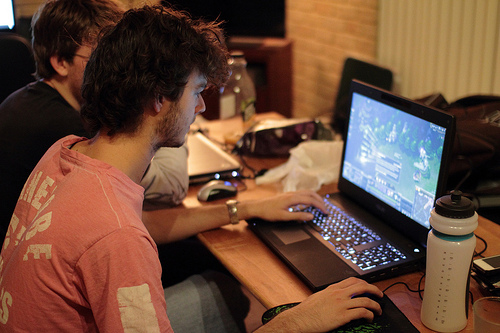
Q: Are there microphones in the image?
A: No, there are no microphones.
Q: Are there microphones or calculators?
A: No, there are no microphones or calculators.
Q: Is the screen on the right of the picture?
A: Yes, the screen is on the right of the image.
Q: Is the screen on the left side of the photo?
A: No, the screen is on the right of the image.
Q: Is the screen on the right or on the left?
A: The screen is on the right of the image.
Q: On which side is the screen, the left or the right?
A: The screen is on the right of the image.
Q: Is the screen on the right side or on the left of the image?
A: The screen is on the right of the image.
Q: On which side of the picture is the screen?
A: The screen is on the right of the image.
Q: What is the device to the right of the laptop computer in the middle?
A: The device is a screen.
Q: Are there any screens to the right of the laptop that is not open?
A: Yes, there is a screen to the right of the laptop.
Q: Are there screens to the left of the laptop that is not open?
A: No, the screen is to the right of the laptop computer.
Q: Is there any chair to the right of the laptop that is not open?
A: No, there is a screen to the right of the laptop computer.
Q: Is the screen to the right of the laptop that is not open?
A: Yes, the screen is to the right of the laptop.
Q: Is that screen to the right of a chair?
A: No, the screen is to the right of the laptop.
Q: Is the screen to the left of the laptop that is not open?
A: No, the screen is to the right of the laptop computer.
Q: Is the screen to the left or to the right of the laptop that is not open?
A: The screen is to the right of the laptop.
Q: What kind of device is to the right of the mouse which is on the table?
A: The device is a screen.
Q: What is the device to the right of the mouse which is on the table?
A: The device is a screen.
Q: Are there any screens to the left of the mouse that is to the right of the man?
A: No, the screen is to the right of the mouse.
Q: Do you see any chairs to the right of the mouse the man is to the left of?
A: No, there is a screen to the right of the computer mouse.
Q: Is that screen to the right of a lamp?
A: No, the screen is to the right of the mouse.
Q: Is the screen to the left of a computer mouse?
A: No, the screen is to the right of a computer mouse.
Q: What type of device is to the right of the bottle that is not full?
A: The device is a screen.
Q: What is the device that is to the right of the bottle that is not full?
A: The device is a screen.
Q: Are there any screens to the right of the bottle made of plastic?
A: Yes, there is a screen to the right of the bottle.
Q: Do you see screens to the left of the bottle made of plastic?
A: No, the screen is to the right of the bottle.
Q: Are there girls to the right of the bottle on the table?
A: No, there is a screen to the right of the bottle.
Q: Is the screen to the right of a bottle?
A: Yes, the screen is to the right of a bottle.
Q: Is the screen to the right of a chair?
A: No, the screen is to the right of a bottle.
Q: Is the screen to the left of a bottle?
A: No, the screen is to the right of a bottle.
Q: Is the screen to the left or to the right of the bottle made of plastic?
A: The screen is to the right of the bottle.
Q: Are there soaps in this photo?
A: No, there are no soaps.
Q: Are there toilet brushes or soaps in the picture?
A: No, there are no soaps or toilet brushes.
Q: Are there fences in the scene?
A: No, there are no fences.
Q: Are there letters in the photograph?
A: Yes, there are letters.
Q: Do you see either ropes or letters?
A: Yes, there are letters.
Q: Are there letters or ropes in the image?
A: Yes, there are letters.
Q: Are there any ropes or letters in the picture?
A: Yes, there are letters.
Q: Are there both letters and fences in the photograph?
A: No, there are letters but no fences.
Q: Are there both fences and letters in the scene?
A: No, there are letters but no fences.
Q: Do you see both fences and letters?
A: No, there are letters but no fences.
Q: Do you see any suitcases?
A: No, there are no suitcases.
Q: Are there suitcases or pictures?
A: No, there are no suitcases or pictures.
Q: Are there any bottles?
A: Yes, there is a bottle.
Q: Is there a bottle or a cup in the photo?
A: Yes, there is a bottle.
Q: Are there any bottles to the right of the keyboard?
A: Yes, there is a bottle to the right of the keyboard.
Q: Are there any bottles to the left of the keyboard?
A: No, the bottle is to the right of the keyboard.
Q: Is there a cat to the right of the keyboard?
A: No, there is a bottle to the right of the keyboard.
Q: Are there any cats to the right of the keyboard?
A: No, there is a bottle to the right of the keyboard.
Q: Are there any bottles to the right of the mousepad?
A: Yes, there is a bottle to the right of the mousepad.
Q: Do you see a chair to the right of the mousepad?
A: No, there is a bottle to the right of the mousepad.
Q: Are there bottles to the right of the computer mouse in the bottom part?
A: Yes, there is a bottle to the right of the mouse.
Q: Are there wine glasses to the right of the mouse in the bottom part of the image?
A: No, there is a bottle to the right of the mouse.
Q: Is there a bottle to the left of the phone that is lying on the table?
A: Yes, there is a bottle to the left of the telephone.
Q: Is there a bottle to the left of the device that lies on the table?
A: Yes, there is a bottle to the left of the telephone.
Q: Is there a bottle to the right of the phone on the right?
A: No, the bottle is to the left of the telephone.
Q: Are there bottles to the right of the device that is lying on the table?
A: No, the bottle is to the left of the telephone.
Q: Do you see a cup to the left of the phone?
A: No, there is a bottle to the left of the phone.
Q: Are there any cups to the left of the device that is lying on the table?
A: No, there is a bottle to the left of the phone.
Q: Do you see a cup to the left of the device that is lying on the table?
A: No, there is a bottle to the left of the phone.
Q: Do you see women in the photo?
A: No, there are no women.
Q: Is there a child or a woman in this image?
A: No, there are no women or children.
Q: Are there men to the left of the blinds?
A: Yes, there is a man to the left of the blinds.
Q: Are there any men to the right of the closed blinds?
A: No, the man is to the left of the blinds.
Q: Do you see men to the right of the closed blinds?
A: No, the man is to the left of the blinds.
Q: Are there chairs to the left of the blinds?
A: No, there is a man to the left of the blinds.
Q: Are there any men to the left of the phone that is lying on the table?
A: Yes, there is a man to the left of the phone.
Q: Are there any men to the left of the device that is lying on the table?
A: Yes, there is a man to the left of the phone.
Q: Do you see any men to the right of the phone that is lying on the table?
A: No, the man is to the left of the phone.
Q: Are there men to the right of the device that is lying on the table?
A: No, the man is to the left of the phone.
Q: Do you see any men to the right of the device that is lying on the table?
A: No, the man is to the left of the phone.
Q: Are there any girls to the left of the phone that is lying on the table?
A: No, there is a man to the left of the telephone.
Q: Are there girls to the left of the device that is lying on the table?
A: No, there is a man to the left of the telephone.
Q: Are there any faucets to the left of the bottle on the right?
A: No, there is a man to the left of the bottle.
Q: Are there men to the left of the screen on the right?
A: Yes, there is a man to the left of the screen.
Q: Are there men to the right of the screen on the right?
A: No, the man is to the left of the screen.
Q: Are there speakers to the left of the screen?
A: No, there is a man to the left of the screen.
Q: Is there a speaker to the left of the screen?
A: No, there is a man to the left of the screen.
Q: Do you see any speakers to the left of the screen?
A: No, there is a man to the left of the screen.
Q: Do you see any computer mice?
A: Yes, there is a computer mouse.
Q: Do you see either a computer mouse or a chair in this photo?
A: Yes, there is a computer mouse.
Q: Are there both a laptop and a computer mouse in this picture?
A: Yes, there are both a computer mouse and a laptop.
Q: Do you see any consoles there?
A: No, there are no consoles.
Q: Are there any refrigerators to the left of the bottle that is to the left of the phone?
A: No, there is a computer mouse to the left of the bottle.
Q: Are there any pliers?
A: No, there are no pliers.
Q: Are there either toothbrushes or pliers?
A: No, there are no pliers or toothbrushes.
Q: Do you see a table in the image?
A: Yes, there is a table.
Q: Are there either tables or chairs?
A: Yes, there is a table.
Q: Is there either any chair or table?
A: Yes, there is a table.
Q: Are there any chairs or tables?
A: Yes, there is a table.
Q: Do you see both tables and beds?
A: No, there is a table but no beds.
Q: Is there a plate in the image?
A: No, there are no plates.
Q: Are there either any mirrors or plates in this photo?
A: No, there are no plates or mirrors.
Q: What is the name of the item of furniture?
A: The piece of furniture is a table.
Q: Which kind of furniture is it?
A: The piece of furniture is a table.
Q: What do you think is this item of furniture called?
A: This is a table.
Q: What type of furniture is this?
A: This is a table.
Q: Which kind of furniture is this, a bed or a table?
A: This is a table.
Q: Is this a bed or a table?
A: This is a table.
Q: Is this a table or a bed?
A: This is a table.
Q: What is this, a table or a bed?
A: This is a table.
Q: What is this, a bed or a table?
A: This is a table.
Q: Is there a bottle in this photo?
A: Yes, there is a bottle.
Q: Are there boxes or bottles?
A: Yes, there is a bottle.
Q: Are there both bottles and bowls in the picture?
A: No, there is a bottle but no bowls.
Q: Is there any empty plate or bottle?
A: Yes, there is an empty bottle.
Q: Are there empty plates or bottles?
A: Yes, there is an empty bottle.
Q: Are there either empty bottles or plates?
A: Yes, there is an empty bottle.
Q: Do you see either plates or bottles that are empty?
A: Yes, the bottle is empty.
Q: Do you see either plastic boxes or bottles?
A: Yes, there is a plastic bottle.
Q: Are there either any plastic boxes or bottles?
A: Yes, there is a plastic bottle.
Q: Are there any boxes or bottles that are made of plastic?
A: Yes, the bottle is made of plastic.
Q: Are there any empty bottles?
A: Yes, there is an empty bottle.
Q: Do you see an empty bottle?
A: Yes, there is an empty bottle.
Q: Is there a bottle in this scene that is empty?
A: Yes, there is a bottle that is empty.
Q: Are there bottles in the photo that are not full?
A: Yes, there is a empty bottle.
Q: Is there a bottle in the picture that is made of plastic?
A: Yes, there is a bottle that is made of plastic.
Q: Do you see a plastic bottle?
A: Yes, there is a bottle that is made of plastic.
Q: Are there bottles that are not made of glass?
A: Yes, there is a bottle that is made of plastic.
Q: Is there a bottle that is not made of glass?
A: Yes, there is a bottle that is made of plastic.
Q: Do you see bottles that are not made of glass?
A: Yes, there is a bottle that is made of plastic.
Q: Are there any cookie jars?
A: No, there are no cookie jars.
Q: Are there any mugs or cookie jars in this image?
A: No, there are no cookie jars or mugs.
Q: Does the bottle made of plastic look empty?
A: Yes, the bottle is empty.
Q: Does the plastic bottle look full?
A: No, the bottle is empty.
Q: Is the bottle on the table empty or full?
A: The bottle is empty.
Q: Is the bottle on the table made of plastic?
A: Yes, the bottle is made of plastic.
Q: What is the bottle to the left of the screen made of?
A: The bottle is made of plastic.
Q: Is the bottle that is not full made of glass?
A: No, the bottle is made of plastic.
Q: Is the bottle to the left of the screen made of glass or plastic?
A: The bottle is made of plastic.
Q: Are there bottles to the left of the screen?
A: Yes, there is a bottle to the left of the screen.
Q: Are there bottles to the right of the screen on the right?
A: No, the bottle is to the left of the screen.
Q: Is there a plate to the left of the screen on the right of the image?
A: No, there is a bottle to the left of the screen.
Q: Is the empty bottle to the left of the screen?
A: Yes, the bottle is to the left of the screen.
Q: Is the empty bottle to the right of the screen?
A: No, the bottle is to the left of the screen.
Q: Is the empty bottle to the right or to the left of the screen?
A: The bottle is to the left of the screen.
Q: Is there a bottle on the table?
A: Yes, there is a bottle on the table.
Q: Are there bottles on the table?
A: Yes, there is a bottle on the table.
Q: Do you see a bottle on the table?
A: Yes, there is a bottle on the table.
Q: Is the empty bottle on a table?
A: Yes, the bottle is on a table.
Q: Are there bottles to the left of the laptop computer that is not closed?
A: Yes, there is a bottle to the left of the laptop.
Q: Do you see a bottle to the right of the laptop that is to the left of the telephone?
A: No, the bottle is to the left of the laptop.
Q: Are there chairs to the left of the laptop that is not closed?
A: No, there is a bottle to the left of the laptop.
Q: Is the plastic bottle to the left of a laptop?
A: Yes, the bottle is to the left of a laptop.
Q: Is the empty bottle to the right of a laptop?
A: No, the bottle is to the left of a laptop.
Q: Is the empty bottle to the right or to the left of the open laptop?
A: The bottle is to the left of the laptop.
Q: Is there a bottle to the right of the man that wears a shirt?
A: Yes, there is a bottle to the right of the man.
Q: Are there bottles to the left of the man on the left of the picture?
A: No, the bottle is to the right of the man.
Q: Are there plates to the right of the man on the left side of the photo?
A: No, there is a bottle to the right of the man.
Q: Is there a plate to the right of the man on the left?
A: No, there is a bottle to the right of the man.